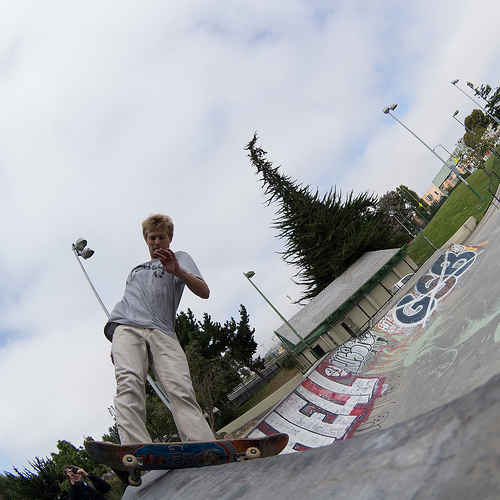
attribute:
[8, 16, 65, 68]
clouds — white 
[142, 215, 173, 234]
hair —  blonde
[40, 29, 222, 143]
cloud — white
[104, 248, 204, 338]
shirt — grey 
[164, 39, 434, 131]
sky — blue 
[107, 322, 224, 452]
pants — khaki 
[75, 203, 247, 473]
man — young 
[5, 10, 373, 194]
sky — blue 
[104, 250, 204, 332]
tee shirt —  tee ,  short sleeve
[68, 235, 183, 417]
post — metal 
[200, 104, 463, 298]
tree —  pine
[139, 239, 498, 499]
ramp — for skateboard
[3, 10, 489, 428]
clouds — white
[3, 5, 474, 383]
clouds — white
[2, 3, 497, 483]
sky — blue 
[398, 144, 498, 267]
grassy area — grassy 